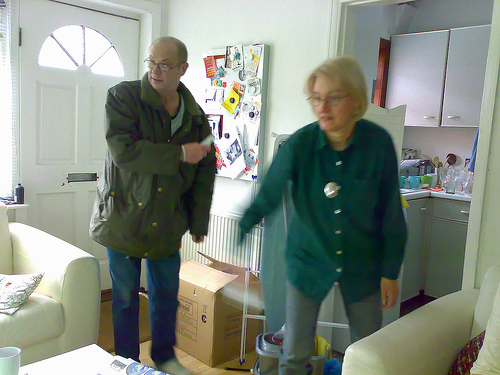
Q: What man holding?
A: Game controller.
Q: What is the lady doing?
A: Playing video game.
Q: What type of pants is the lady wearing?
A: Jeans.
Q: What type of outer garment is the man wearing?
A: Jacket.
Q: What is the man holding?
A: Game controler.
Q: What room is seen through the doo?
A: Kitchen.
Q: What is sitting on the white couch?
A: Pillow.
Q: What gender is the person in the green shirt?
A: Female.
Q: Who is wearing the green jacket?
A: The man.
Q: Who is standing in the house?
A: The man and woman.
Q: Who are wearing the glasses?
A: The two people.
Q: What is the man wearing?
A: A green jacket.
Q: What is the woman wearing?
A: A blue color shirt and grey pants.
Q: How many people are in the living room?
A: Two.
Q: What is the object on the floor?
A: A cardboard box.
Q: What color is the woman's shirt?
A: Green.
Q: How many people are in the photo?
A: Two.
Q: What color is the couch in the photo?
A: White.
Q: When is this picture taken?
A: Daytime.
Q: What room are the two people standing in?
A: Living room.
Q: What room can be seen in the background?
A: Kitchen.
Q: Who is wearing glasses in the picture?
A: The man and the woman.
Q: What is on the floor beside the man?
A: Cardboard box.